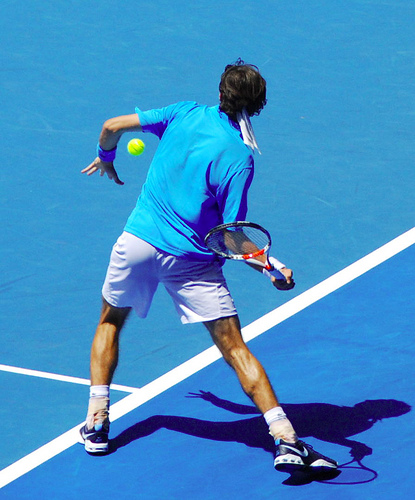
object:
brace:
[82, 382, 111, 430]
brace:
[261, 406, 300, 452]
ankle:
[263, 409, 296, 434]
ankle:
[88, 388, 113, 409]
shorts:
[100, 229, 240, 327]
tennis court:
[0, 0, 413, 498]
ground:
[0, 1, 415, 499]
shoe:
[272, 434, 340, 476]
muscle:
[235, 360, 263, 396]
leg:
[87, 269, 138, 426]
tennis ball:
[125, 138, 147, 158]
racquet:
[203, 217, 296, 294]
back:
[146, 114, 231, 241]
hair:
[218, 56, 269, 124]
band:
[234, 108, 262, 156]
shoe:
[78, 419, 113, 455]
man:
[75, 57, 340, 477]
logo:
[279, 441, 310, 461]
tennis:
[78, 57, 341, 480]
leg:
[190, 279, 305, 437]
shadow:
[105, 388, 415, 485]